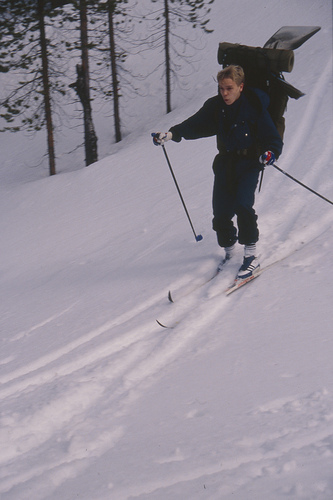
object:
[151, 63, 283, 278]
skier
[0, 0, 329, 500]
mountain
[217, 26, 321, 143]
backpack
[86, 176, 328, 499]
stracks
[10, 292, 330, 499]
snow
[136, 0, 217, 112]
tree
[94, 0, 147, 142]
tree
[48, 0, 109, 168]
tree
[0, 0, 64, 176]
tree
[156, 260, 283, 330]
ski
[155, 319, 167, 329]
tip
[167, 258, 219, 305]
ski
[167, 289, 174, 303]
tip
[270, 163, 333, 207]
pole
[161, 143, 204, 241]
pole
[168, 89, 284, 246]
skisuit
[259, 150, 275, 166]
glove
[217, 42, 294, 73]
bedroll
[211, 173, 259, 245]
pants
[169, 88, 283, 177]
jacket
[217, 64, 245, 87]
hair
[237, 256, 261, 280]
boot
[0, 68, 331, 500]
tracks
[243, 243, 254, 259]
sock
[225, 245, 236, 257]
sock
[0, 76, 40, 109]
branch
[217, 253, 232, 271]
boot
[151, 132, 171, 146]
glove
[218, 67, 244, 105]
head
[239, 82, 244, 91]
ear